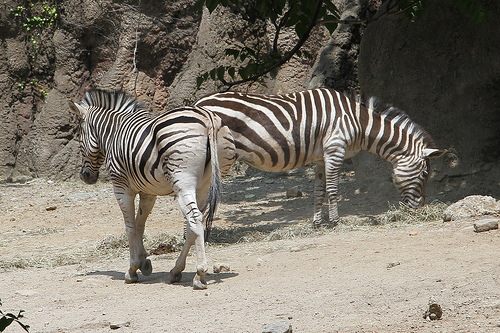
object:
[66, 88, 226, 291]
zebra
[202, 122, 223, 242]
tail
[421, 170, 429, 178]
eye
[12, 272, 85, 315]
rocks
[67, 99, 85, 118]
ear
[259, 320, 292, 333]
rock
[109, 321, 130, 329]
rock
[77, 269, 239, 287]
shadow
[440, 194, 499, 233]
two rocks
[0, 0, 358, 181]
rock wall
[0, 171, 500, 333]
ground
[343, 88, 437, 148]
mane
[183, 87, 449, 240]
zebra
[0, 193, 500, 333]
hill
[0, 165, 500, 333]
dirt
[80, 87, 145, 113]
mane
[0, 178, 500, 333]
sand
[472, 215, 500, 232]
rock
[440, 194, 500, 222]
rock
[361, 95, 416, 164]
neck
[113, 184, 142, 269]
leg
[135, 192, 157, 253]
leg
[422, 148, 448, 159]
ear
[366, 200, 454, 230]
grass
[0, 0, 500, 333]
enclosure